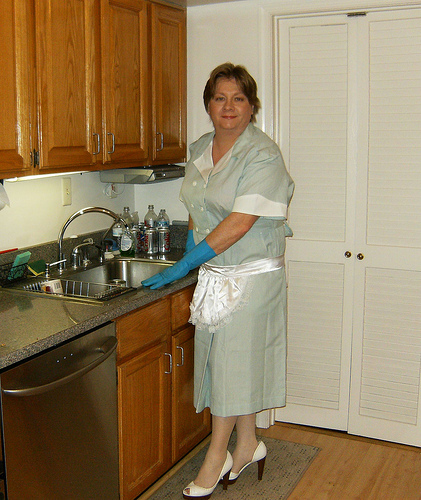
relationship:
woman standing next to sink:
[141, 63, 294, 490] [0, 260, 181, 306]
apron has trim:
[185, 249, 288, 334] [186, 273, 250, 332]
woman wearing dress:
[141, 63, 293, 500] [175, 124, 295, 416]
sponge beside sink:
[3, 251, 34, 285] [18, 254, 177, 305]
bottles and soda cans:
[154, 208, 170, 255] [157, 224, 172, 255]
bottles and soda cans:
[143, 203, 156, 253] [142, 226, 156, 254]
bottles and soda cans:
[118, 203, 134, 253] [127, 226, 142, 254]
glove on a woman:
[141, 240, 215, 288] [141, 63, 294, 490]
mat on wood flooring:
[138, 423, 324, 500] [134, 411, 420, 500]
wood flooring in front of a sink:
[134, 411, 420, 500] [58, 209, 184, 305]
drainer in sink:
[27, 276, 121, 308] [29, 255, 188, 301]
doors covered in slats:
[268, 33, 417, 446] [288, 27, 346, 161]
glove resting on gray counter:
[141, 238, 219, 287] [2, 246, 195, 369]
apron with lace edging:
[185, 257, 286, 333] [186, 298, 247, 336]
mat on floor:
[147, 427, 321, 497] [140, 424, 419, 496]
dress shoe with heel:
[179, 479, 208, 497] [221, 469, 230, 490]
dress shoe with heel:
[250, 442, 268, 461] [253, 457, 269, 484]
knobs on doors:
[340, 244, 374, 266] [268, 33, 417, 446]